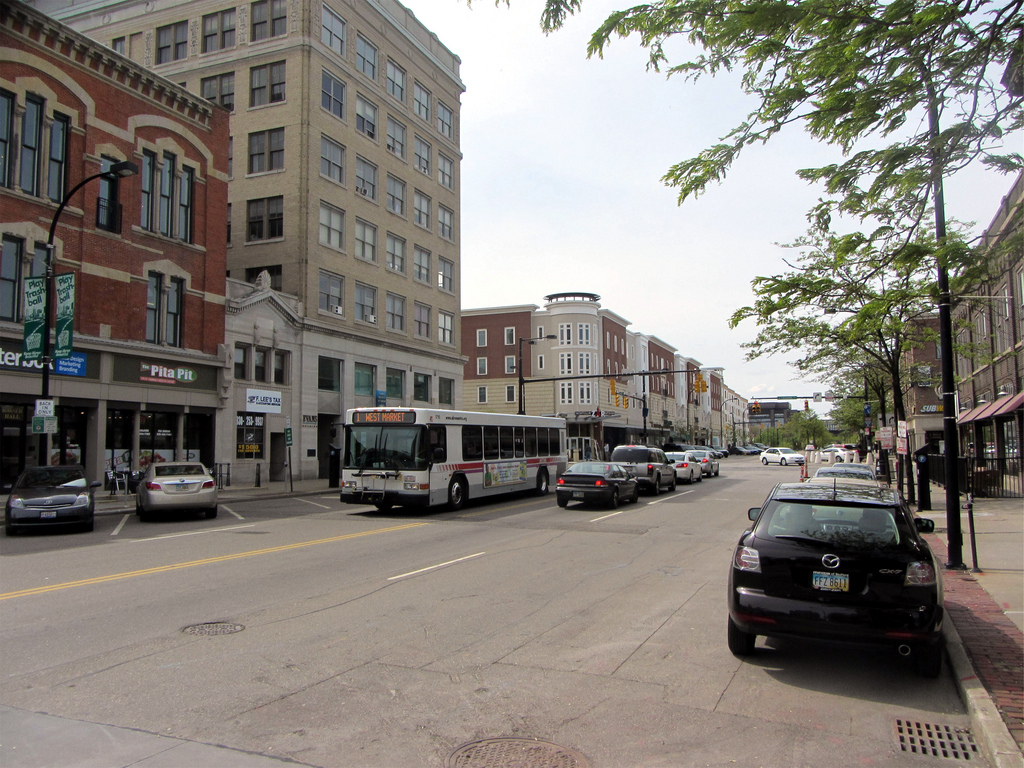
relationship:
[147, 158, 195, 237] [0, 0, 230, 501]
window on a stories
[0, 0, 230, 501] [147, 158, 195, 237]
stories has a window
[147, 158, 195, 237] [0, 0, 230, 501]
window on stories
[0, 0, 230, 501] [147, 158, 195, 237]
stories with a window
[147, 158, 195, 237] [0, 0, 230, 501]
window in a stories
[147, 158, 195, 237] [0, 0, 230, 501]
window inside a stories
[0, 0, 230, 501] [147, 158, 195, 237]
stories encloses a window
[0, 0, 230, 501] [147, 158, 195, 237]
stories with window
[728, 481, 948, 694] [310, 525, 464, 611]
car on a street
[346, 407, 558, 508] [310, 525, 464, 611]
bus on street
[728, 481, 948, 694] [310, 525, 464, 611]
car parked on street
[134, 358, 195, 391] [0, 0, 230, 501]
sign on stories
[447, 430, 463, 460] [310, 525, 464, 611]
white bus on street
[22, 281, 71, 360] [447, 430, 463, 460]
banners are green and white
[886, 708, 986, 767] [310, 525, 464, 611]
sewer grate in street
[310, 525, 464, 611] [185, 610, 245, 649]
street has two man holes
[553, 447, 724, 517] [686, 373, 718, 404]
cars stopped at light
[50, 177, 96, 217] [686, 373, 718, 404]
pole on street light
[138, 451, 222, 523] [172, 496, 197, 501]
car parked silver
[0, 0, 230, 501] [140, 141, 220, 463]
stories has three stories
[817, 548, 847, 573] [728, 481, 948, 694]
logo on car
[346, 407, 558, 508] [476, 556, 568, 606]
bus on road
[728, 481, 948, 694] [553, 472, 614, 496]
car has stopped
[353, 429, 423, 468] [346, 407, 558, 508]
windshield of bus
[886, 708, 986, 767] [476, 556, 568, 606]
sewer vent on road